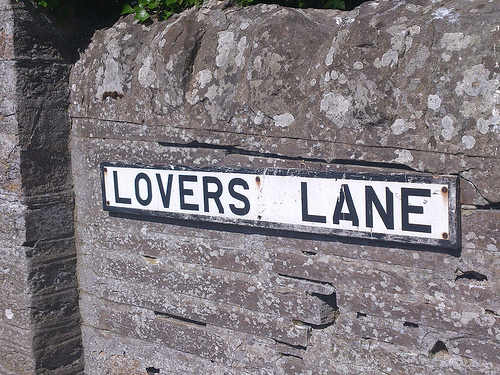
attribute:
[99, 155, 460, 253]
sign — black, white, rectangular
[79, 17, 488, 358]
wall — limestone, stone, damage, gray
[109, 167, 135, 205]
l — black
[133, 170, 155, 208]
o — black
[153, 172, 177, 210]
v — black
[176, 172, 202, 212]
e — black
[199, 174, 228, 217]
r — black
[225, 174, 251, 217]
s — black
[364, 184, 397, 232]
n — black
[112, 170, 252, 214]
letters — black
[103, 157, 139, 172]
edge — black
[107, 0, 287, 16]
leaves — green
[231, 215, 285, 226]
paint — chipped